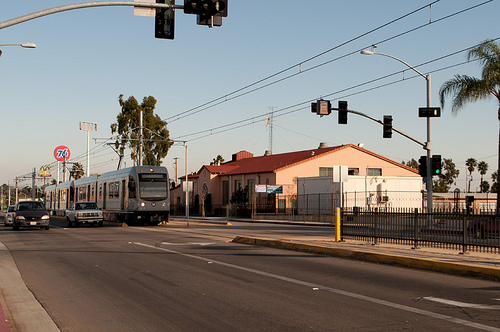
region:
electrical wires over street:
[171, 8, 478, 153]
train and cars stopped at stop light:
[6, 147, 181, 237]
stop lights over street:
[0, 4, 242, 66]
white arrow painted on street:
[157, 221, 221, 261]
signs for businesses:
[32, 140, 71, 190]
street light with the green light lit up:
[410, 146, 450, 181]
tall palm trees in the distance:
[462, 149, 495, 190]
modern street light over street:
[362, 43, 447, 223]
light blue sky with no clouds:
[60, 49, 140, 77]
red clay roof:
[214, 145, 309, 186]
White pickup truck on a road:
[64, 199, 104, 229]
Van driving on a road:
[10, 198, 51, 232]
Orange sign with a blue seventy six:
[52, 143, 71, 161]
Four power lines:
[2, 0, 498, 189]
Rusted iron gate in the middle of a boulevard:
[339, 205, 499, 252]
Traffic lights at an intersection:
[307, 95, 428, 151]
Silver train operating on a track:
[42, 164, 168, 226]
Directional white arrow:
[159, 235, 219, 250]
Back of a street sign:
[332, 164, 350, 208]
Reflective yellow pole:
[331, 203, 343, 241]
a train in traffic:
[12, 153, 188, 238]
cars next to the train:
[4, 194, 121, 241]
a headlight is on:
[122, 187, 173, 220]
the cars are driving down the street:
[0, 189, 127, 256]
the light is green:
[416, 147, 456, 192]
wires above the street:
[144, 49, 470, 144]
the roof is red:
[194, 128, 364, 185]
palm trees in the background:
[458, 147, 487, 189]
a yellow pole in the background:
[304, 198, 356, 248]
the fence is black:
[362, 205, 497, 242]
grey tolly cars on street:
[46, 165, 171, 217]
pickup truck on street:
[65, 202, 102, 226]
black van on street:
[16, 200, 48, 227]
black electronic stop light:
[336, 101, 393, 138]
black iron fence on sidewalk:
[341, 206, 498, 256]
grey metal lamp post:
[79, 121, 97, 172]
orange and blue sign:
[53, 145, 69, 162]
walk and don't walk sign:
[418, 107, 440, 118]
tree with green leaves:
[111, 93, 173, 165]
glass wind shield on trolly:
[139, 178, 168, 200]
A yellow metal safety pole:
[327, 203, 353, 244]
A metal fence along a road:
[365, 195, 430, 261]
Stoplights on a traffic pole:
[302, 90, 412, 153]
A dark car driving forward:
[5, 194, 60, 236]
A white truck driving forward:
[61, 193, 111, 231]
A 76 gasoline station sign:
[48, 139, 74, 164]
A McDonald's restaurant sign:
[34, 159, 54, 182]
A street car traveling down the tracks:
[39, 157, 181, 232]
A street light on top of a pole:
[358, 40, 438, 96]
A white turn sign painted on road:
[154, 227, 236, 258]